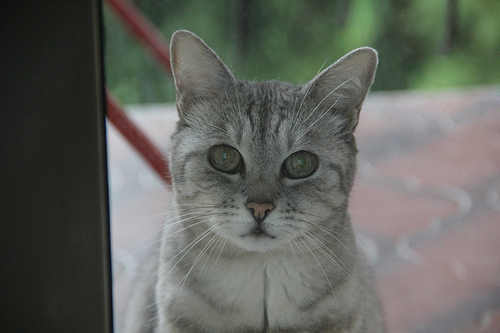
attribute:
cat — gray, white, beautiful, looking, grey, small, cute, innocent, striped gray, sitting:
[115, 26, 389, 332]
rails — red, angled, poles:
[103, 0, 171, 185]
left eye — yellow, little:
[281, 146, 318, 182]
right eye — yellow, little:
[207, 141, 242, 176]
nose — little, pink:
[248, 198, 272, 221]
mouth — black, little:
[235, 224, 276, 240]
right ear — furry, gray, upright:
[166, 25, 234, 100]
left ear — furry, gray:
[302, 40, 378, 128]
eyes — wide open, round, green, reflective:
[204, 142, 320, 179]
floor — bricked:
[108, 84, 499, 332]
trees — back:
[102, 1, 499, 107]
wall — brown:
[1, 0, 113, 332]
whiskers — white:
[280, 209, 372, 305]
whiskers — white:
[122, 201, 234, 322]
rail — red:
[103, 93, 172, 186]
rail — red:
[110, 1, 170, 73]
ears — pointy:
[167, 28, 379, 115]